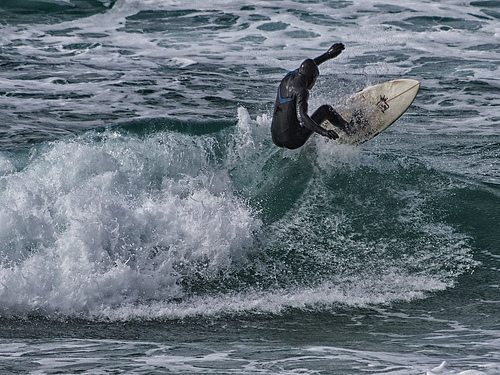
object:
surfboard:
[315, 79, 421, 146]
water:
[0, 1, 499, 375]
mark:
[376, 95, 390, 113]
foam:
[1, 1, 500, 375]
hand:
[327, 42, 346, 58]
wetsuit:
[271, 43, 362, 149]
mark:
[277, 86, 293, 104]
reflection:
[328, 48, 333, 53]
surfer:
[271, 43, 361, 150]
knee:
[319, 104, 331, 110]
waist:
[271, 121, 302, 133]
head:
[299, 58, 320, 89]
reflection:
[302, 64, 305, 67]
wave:
[0, 114, 499, 322]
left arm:
[295, 53, 330, 73]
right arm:
[296, 89, 327, 136]